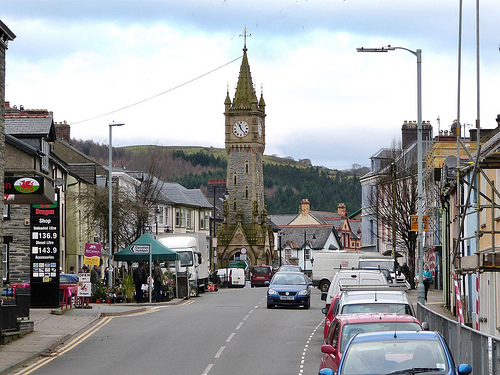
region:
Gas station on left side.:
[8, 172, 86, 345]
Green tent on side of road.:
[118, 216, 180, 273]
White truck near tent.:
[168, 225, 250, 337]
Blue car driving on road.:
[266, 263, 318, 323]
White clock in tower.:
[227, 110, 278, 166]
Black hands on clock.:
[232, 123, 255, 138]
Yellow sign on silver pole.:
[402, 207, 452, 255]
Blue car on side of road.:
[368, 321, 450, 368]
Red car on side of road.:
[320, 302, 430, 347]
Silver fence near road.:
[421, 303, 498, 359]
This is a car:
[256, 268, 313, 317]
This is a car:
[267, 251, 314, 279]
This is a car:
[250, 255, 273, 289]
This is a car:
[338, 325, 478, 374]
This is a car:
[312, 308, 439, 350]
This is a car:
[325, 287, 429, 314]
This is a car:
[325, 272, 405, 297]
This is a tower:
[219, 28, 294, 268]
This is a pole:
[106, 113, 129, 316]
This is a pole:
[401, 35, 437, 331]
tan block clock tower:
[222, 48, 267, 247]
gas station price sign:
[31, 203, 63, 305]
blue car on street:
[269, 270, 308, 305]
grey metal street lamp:
[108, 121, 118, 303]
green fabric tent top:
[118, 233, 178, 263]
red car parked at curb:
[323, 315, 425, 369]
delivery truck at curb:
[158, 238, 204, 291]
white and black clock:
[234, 118, 249, 136]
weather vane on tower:
[236, 24, 253, 49]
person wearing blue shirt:
[421, 263, 431, 294]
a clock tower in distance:
[215, 25, 271, 279]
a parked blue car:
[317, 329, 472, 373]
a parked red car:
[319, 310, 429, 373]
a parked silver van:
[337, 288, 416, 323]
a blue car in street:
[267, 268, 309, 308]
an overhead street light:
[352, 37, 429, 302]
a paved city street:
[22, 275, 330, 370]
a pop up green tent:
[112, 230, 181, 303]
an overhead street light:
[104, 116, 125, 291]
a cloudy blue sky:
[0, 4, 499, 168]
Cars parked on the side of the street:
[311, 255, 433, 370]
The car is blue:
[263, 259, 313, 312]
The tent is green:
[104, 224, 176, 297]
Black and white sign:
[126, 240, 157, 255]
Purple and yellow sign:
[79, 242, 109, 270]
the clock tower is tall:
[219, 31, 274, 265]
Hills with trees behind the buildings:
[141, 139, 356, 216]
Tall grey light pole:
[363, 34, 436, 287]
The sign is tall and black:
[27, 205, 63, 309]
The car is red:
[326, 309, 428, 364]